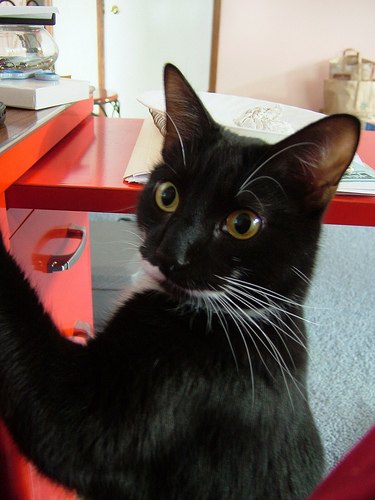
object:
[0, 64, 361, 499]
cat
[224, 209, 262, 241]
eye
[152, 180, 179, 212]
eye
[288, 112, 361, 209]
ear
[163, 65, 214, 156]
ear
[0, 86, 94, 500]
dresser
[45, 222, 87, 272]
handle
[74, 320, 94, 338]
handle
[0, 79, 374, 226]
desk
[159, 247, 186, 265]
nose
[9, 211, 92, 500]
drawer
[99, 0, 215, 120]
door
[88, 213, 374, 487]
carpet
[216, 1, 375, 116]
wall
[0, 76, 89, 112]
plate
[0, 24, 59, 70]
bottle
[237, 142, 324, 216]
whiskers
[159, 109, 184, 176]
whiskers